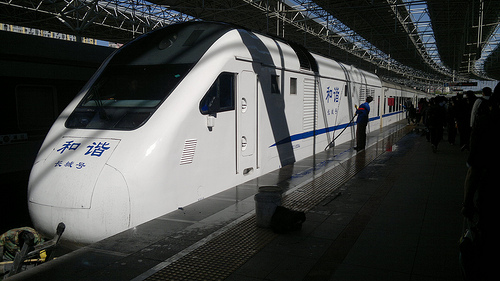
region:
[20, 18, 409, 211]
train on the rail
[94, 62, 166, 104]
window on the train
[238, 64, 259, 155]
door on the train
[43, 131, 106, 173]
lettering on the train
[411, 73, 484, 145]
pedestrians on the platform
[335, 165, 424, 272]
platform beside the train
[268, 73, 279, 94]
window on the train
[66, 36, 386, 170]
car on the train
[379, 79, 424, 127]
car on the train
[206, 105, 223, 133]
mirror on the train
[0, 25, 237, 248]
front of the train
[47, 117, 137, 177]
symbols on the train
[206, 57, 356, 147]
side of the train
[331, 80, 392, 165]
person next to the train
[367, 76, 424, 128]
windows on side of train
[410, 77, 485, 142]
people in the photo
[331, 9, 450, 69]
roof of the place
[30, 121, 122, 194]
blue symbols on train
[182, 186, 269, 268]
white line on ground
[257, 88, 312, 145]
shadow on side of train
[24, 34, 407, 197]
long white train in the station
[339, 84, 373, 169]
man by the train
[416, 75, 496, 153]
people on the platform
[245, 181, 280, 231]
bucket on the ground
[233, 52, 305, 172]
shadow on the train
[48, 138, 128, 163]
blue writing on the front of train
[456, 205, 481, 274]
person holding a bag in left hand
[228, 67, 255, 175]
door to the train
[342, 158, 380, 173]
reflection on the ground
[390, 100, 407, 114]
windows on the train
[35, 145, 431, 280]
water on the walkway in the station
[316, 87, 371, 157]
a man participates in washing the train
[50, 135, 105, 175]
a train has writing in Japanese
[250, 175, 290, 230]
large white buckets used for cleaning the train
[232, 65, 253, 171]
door to the engine car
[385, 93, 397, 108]
a red flag hangs off the white train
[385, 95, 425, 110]
windows in the passenger cars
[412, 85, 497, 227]
People wait to board the train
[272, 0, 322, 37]
a terminal that holds the electric cables for the train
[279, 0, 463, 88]
long skylights stripe the station ceiling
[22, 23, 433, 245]
a white train in a station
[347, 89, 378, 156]
a man dressed in blue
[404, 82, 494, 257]
people waiting to get on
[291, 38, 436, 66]
a metal steel beam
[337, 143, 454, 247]
a concrete walk way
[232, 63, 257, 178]
a door on a train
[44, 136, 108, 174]
blue writing on a train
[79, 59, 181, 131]
a window on a train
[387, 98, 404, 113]
a row of windows on a train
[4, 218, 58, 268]
a man in front of the train